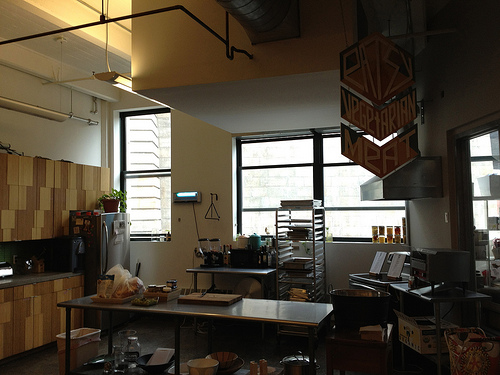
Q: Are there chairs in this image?
A: No, there are no chairs.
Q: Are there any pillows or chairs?
A: No, there are no chairs or pillows.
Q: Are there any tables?
A: Yes, there is a table.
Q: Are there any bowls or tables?
A: Yes, there is a table.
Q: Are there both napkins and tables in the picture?
A: No, there is a table but no napkins.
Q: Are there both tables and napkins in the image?
A: No, there is a table but no napkins.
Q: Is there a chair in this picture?
A: No, there are no chairs.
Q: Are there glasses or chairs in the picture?
A: No, there are no chairs or glasses.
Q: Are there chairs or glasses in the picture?
A: No, there are no chairs or glasses.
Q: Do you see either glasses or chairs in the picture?
A: No, there are no chairs or glasses.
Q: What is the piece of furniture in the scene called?
A: The piece of furniture is a table.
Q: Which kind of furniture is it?
A: The piece of furniture is a table.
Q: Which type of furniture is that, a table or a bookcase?
A: This is a table.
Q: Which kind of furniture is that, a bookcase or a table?
A: This is a table.